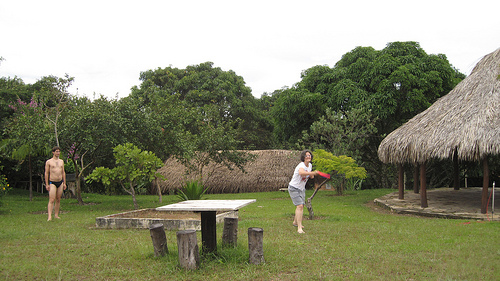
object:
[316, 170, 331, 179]
frisbee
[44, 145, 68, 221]
man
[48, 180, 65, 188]
speedo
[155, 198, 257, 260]
table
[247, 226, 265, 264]
stump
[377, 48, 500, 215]
hut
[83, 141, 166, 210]
tree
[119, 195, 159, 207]
grass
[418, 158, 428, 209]
wood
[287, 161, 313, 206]
suit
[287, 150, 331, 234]
person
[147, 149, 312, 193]
roof